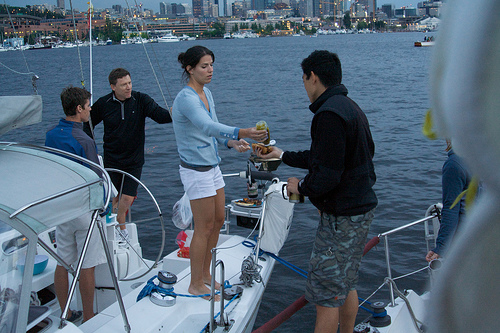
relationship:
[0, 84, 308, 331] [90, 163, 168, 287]
sailboat has steering wheel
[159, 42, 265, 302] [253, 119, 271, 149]
girl squeezing ketchup bottle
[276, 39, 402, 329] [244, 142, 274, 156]
man holding hotdog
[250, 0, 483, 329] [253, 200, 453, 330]
sailboat has safety rail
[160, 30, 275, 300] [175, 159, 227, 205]
woman wearing shorts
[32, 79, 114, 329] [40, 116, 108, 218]
man wearing jacket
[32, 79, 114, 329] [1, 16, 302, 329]
man on boat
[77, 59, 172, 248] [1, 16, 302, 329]
man on boat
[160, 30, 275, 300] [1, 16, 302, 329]
woman on boat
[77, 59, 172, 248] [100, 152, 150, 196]
man wearing shorts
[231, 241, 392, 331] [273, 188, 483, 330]
rope on boat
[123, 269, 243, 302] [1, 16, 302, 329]
rope on boat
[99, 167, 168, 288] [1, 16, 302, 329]
steering wheel on boat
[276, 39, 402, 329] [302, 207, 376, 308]
man wearing shorts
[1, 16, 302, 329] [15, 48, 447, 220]
boat in rivers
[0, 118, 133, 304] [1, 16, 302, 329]
shelter on boat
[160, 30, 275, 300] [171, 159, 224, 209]
woman wearing shorts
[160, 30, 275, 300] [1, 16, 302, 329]
woman standing on a boat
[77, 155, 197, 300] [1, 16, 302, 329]
wheel on boat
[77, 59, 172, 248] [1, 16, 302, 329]
man standing on a boat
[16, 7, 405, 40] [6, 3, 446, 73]
city in background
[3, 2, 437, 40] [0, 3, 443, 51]
buildings in background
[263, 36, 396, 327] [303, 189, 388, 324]
guy wearing shorts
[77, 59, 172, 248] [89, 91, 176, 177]
man wearing black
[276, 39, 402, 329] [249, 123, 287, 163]
man holding hotdog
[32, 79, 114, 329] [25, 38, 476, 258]
man looking at water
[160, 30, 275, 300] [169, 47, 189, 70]
woman with tail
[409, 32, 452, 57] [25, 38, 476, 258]
boat in water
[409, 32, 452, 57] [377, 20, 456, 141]
boat in distance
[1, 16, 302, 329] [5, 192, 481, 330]
boat parked at harbor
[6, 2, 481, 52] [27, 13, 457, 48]
skyline overlooking harbor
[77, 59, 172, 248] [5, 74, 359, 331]
man standing on a boat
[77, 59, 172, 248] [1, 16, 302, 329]
man talking on a boat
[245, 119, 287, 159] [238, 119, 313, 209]
hotdog in hand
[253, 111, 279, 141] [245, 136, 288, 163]
condiment on hotdog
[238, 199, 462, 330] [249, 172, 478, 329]
railing on boat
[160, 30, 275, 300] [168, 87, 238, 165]
woman wearing sweater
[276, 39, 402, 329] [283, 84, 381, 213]
man wearing sweater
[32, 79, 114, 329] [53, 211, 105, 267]
man wearing shorts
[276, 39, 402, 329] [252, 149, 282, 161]
man holding hotdog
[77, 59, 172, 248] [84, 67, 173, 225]
man wearing shorts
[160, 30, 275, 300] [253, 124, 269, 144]
woman squeezing ketchup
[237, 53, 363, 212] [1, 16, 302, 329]
mans hotdog on boat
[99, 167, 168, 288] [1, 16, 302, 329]
steering wheel of boat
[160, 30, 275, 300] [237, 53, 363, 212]
woman condiment on mans hotdog